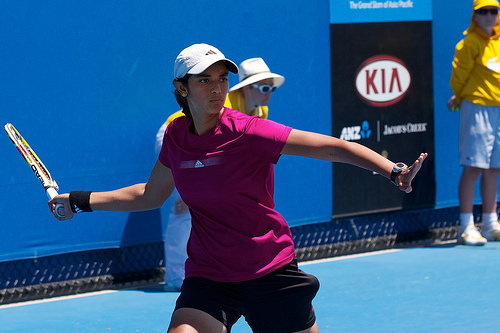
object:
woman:
[46, 42, 428, 332]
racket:
[4, 121, 65, 215]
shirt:
[154, 105, 295, 282]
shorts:
[170, 253, 319, 332]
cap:
[170, 42, 240, 81]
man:
[155, 54, 286, 290]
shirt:
[166, 91, 269, 126]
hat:
[229, 56, 285, 92]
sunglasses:
[251, 81, 276, 95]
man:
[446, 1, 499, 247]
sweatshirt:
[449, 12, 499, 106]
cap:
[470, 0, 499, 11]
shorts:
[458, 96, 499, 172]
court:
[1, 234, 499, 333]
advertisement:
[326, 0, 435, 223]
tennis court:
[1, 1, 499, 332]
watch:
[388, 160, 406, 185]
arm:
[251, 117, 400, 182]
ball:
[297, 270, 321, 300]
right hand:
[47, 191, 74, 222]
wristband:
[68, 188, 94, 214]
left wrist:
[388, 161, 399, 186]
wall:
[1, 0, 499, 257]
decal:
[354, 56, 410, 106]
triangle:
[193, 159, 205, 168]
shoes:
[453, 219, 486, 244]